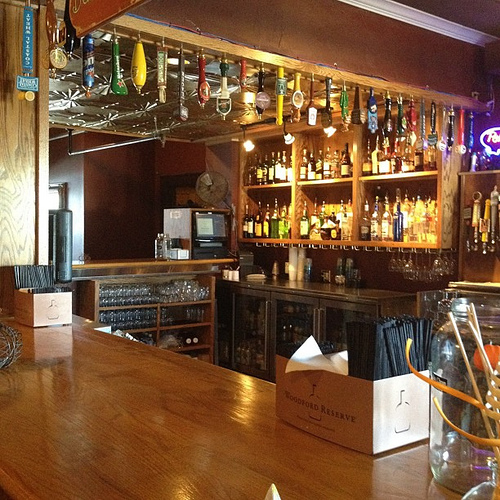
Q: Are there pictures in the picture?
A: No, there are no pictures.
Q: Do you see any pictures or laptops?
A: No, there are no pictures or laptops.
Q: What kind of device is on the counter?
A: The device is a monitor.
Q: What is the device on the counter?
A: The device is a monitor.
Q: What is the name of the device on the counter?
A: The device is a monitor.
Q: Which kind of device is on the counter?
A: The device is a monitor.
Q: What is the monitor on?
A: The monitor is on the counter.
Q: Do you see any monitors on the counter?
A: Yes, there is a monitor on the counter.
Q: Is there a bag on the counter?
A: No, there is a monitor on the counter.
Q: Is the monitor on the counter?
A: Yes, the monitor is on the counter.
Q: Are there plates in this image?
A: No, there are no plates.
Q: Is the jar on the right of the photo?
A: Yes, the jar is on the right of the image.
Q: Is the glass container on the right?
A: Yes, the jar is on the right of the image.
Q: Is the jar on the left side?
A: No, the jar is on the right of the image.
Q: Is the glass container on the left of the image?
A: No, the jar is on the right of the image.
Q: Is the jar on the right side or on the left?
A: The jar is on the right of the image.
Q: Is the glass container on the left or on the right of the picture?
A: The jar is on the right of the image.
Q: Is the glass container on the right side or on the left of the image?
A: The jar is on the right of the image.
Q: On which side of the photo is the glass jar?
A: The jar is on the right of the image.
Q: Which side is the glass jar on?
A: The jar is on the right of the image.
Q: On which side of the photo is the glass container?
A: The jar is on the right of the image.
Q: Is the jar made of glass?
A: Yes, the jar is made of glass.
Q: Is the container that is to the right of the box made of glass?
A: Yes, the jar is made of glass.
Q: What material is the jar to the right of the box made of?
A: The jar is made of glass.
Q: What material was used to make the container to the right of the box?
A: The jar is made of glass.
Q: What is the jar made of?
A: The jar is made of glass.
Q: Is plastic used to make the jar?
A: No, the jar is made of glass.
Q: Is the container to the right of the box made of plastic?
A: No, the jar is made of glass.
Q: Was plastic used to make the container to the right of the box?
A: No, the jar is made of glass.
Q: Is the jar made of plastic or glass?
A: The jar is made of glass.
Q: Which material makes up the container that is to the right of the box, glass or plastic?
A: The jar is made of glass.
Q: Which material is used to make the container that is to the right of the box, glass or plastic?
A: The jar is made of glass.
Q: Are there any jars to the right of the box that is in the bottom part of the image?
A: Yes, there is a jar to the right of the box.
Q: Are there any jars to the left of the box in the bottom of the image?
A: No, the jar is to the right of the box.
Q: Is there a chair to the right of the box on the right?
A: No, there is a jar to the right of the box.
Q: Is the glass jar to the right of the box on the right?
A: Yes, the jar is to the right of the box.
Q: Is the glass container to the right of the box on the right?
A: Yes, the jar is to the right of the box.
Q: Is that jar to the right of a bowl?
A: No, the jar is to the right of the box.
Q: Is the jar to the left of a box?
A: No, the jar is to the right of a box.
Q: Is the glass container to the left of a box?
A: No, the jar is to the right of a box.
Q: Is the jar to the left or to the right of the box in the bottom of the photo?
A: The jar is to the right of the box.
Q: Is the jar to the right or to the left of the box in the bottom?
A: The jar is to the right of the box.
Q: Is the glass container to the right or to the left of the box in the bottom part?
A: The jar is to the right of the box.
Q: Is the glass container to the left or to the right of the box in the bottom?
A: The jar is to the right of the box.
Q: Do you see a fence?
A: No, there are no fences.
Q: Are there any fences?
A: No, there are no fences.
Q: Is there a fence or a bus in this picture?
A: No, there are no fences or buses.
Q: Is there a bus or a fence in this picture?
A: No, there are no fences or buses.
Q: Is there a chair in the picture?
A: No, there are no chairs.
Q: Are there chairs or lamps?
A: No, there are no chairs or lamps.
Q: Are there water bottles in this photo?
A: No, there are no water bottles.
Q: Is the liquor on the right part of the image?
A: Yes, the liquor is on the right of the image.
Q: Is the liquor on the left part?
A: No, the liquor is on the right of the image.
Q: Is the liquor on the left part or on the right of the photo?
A: The liquor is on the right of the image.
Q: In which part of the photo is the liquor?
A: The liquor is on the right of the image.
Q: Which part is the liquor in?
A: The liquor is on the right of the image.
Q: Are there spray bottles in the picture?
A: No, there are no spray bottles.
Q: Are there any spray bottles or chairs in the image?
A: No, there are no spray bottles or chairs.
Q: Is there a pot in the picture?
A: No, there are no pots.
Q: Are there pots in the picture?
A: No, there are no pots.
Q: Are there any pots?
A: No, there are no pots.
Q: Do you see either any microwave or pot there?
A: No, there are no pots or microwaves.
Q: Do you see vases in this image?
A: No, there are no vases.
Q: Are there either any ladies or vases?
A: No, there are no vases or ladies.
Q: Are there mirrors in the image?
A: No, there are no mirrors.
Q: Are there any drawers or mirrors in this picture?
A: No, there are no mirrors or drawers.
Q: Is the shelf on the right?
A: Yes, the shelf is on the right of the image.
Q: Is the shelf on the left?
A: No, the shelf is on the right of the image.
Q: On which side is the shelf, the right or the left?
A: The shelf is on the right of the image.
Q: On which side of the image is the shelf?
A: The shelf is on the right of the image.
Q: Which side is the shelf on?
A: The shelf is on the right of the image.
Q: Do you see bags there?
A: No, there are no bags.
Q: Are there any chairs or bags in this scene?
A: No, there are no bags or chairs.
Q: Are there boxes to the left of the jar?
A: Yes, there is a box to the left of the jar.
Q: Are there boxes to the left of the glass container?
A: Yes, there is a box to the left of the jar.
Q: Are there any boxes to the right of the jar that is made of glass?
A: No, the box is to the left of the jar.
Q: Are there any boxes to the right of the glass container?
A: No, the box is to the left of the jar.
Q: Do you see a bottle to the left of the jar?
A: No, there is a box to the left of the jar.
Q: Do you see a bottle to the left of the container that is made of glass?
A: No, there is a box to the left of the jar.